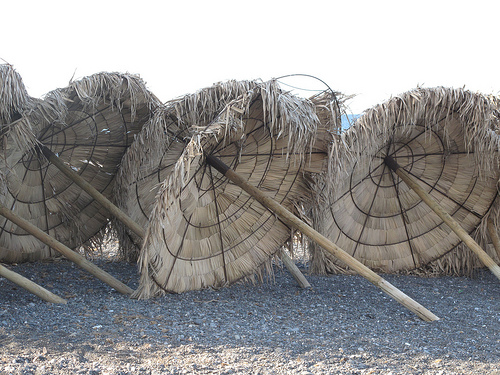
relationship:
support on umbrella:
[205, 180, 219, 195] [130, 82, 348, 307]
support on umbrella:
[211, 199, 222, 236] [142, 96, 335, 296]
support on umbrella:
[208, 208, 234, 235] [130, 82, 348, 307]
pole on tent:
[260, 192, 327, 255] [114, 80, 337, 290]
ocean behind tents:
[343, 112, 351, 127] [122, 84, 342, 285]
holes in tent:
[60, 148, 112, 182] [114, 80, 337, 290]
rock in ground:
[345, 344, 368, 362] [371, 317, 438, 372]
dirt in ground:
[83, 306, 124, 335] [284, 330, 355, 365]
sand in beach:
[322, 334, 371, 356] [28, 293, 484, 359]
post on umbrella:
[213, 160, 441, 323] [133, 71, 439, 325]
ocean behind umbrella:
[343, 112, 360, 134] [306, 87, 496, 287]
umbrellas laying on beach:
[1, 60, 499, 325] [5, 229, 495, 370]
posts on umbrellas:
[0, 148, 500, 320] [1, 60, 499, 325]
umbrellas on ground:
[1, 60, 499, 325] [1, 237, 499, 371]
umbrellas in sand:
[1, 60, 499, 325] [3, 256, 496, 373]